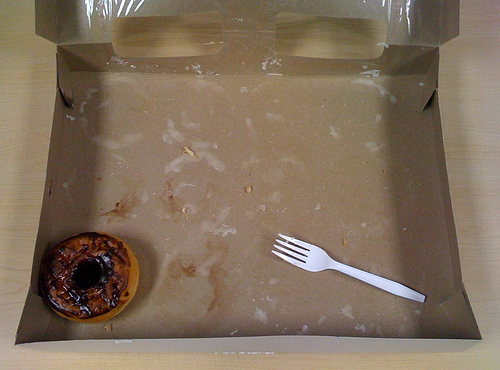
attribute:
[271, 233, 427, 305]
fork — white, plastic, sitting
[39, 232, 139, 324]
doughnut — glazed, solitary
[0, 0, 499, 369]
table — wooden, tan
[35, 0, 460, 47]
plastic — clear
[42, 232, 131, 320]
chocolate — black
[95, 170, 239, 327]
smear — chocolate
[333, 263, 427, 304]
fork handle — white